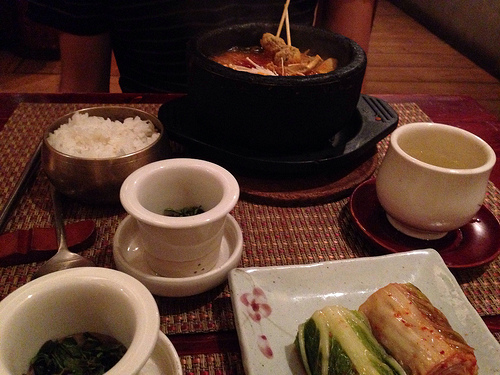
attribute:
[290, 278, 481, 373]
food — Served 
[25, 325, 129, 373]
food — Served 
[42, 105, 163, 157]
food — Served 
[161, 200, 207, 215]
food — Served 